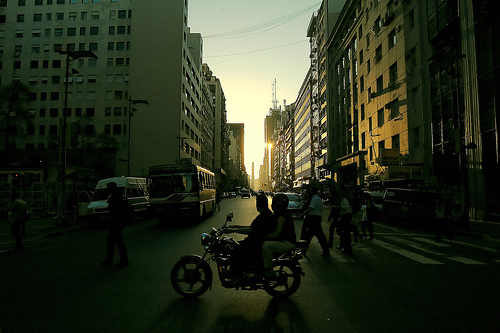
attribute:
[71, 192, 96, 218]
van door — open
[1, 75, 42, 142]
tree — green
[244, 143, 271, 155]
sun — glint